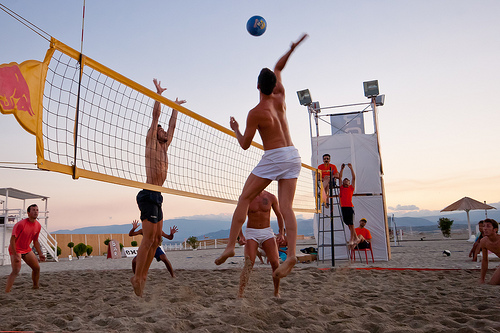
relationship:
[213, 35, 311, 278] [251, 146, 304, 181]
man wearing shorts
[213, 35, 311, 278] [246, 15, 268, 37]
man preparing to hit ball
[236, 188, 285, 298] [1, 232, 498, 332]
man standing in sand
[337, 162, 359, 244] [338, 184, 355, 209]
man wearing a shirt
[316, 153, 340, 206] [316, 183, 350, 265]
referee on a chair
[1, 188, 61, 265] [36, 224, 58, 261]
life guard stand has a ladder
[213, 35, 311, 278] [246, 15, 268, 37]
man spiking ball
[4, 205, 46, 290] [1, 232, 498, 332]
man standing on sand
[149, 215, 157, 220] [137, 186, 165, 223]
logo on shorts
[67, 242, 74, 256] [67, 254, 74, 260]
plant in pot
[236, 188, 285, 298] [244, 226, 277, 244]
man wearing shorts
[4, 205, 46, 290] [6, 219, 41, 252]
man wearing a t-shirt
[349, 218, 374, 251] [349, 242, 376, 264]
man sitting on a chair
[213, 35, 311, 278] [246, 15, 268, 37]
man hitting ball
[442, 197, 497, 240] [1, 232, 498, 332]
umbrella in sand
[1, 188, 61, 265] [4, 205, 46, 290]
life guard stand behind man